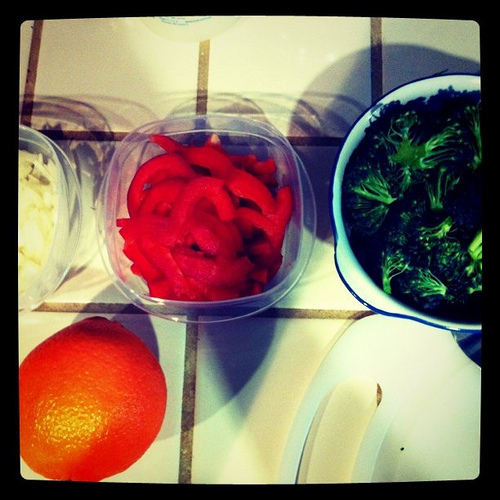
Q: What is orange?
A: The orange.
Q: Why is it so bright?
A: Lights are on.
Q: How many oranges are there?
A: One.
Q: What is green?
A: The brocoli.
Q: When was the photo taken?
A: Day time.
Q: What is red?
A: The peppers.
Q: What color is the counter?
A: White.